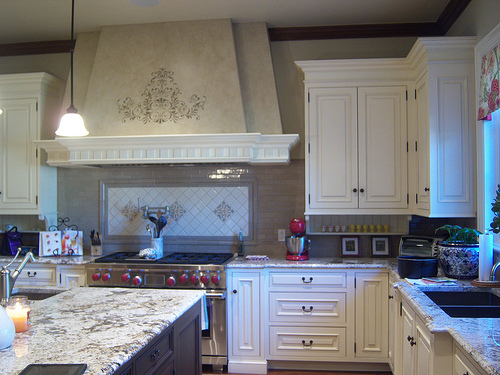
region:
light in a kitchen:
[46, 9, 94, 150]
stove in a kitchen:
[93, 247, 224, 287]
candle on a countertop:
[3, 293, 38, 337]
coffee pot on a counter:
[274, 210, 314, 269]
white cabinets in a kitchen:
[272, 272, 350, 366]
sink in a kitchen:
[436, 286, 489, 324]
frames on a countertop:
[340, 235, 391, 260]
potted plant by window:
[430, 219, 483, 286]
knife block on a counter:
[79, 224, 109, 262]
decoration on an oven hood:
[105, 64, 221, 126]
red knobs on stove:
[84, 268, 220, 291]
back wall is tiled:
[96, 180, 253, 247]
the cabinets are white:
[2, 37, 490, 374]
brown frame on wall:
[1, 0, 478, 60]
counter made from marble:
[0, 287, 204, 373]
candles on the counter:
[1, 294, 31, 352]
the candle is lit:
[9, 292, 31, 337]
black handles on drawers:
[296, 274, 321, 354]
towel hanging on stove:
[198, 287, 219, 341]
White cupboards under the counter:
[231, 270, 449, 372]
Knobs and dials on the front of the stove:
[87, 265, 223, 291]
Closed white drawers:
[267, 271, 353, 359]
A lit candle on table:
[8, 297, 30, 332]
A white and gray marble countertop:
[2, 285, 192, 373]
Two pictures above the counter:
[337, 232, 391, 258]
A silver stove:
[89, 250, 229, 369]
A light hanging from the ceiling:
[54, 5, 91, 142]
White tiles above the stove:
[105, 187, 249, 234]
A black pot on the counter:
[392, 251, 442, 278]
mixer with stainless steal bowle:
[270, 215, 325, 270]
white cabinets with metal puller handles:
[220, 254, 393, 370]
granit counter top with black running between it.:
[50, 268, 215, 358]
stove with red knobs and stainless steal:
[94, 228, 225, 292]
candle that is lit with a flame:
[0, 282, 40, 330]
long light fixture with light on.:
[47, 0, 106, 148]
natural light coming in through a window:
[410, 100, 495, 328]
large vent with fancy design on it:
[37, 18, 289, 177]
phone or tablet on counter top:
[9, 344, 102, 373]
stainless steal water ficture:
[0, 247, 41, 288]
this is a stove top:
[71, 235, 235, 280]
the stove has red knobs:
[75, 258, 235, 303]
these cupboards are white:
[300, 49, 476, 219]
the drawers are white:
[267, 265, 358, 373]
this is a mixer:
[283, 203, 321, 263]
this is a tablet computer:
[15, 353, 90, 373]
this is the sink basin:
[430, 280, 496, 327]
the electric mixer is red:
[275, 210, 319, 264]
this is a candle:
[0, 289, 38, 339]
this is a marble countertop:
[2, 276, 195, 373]